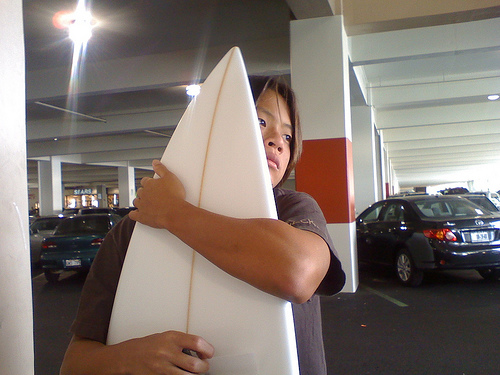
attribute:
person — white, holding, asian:
[55, 77, 344, 374]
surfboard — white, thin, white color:
[106, 43, 301, 374]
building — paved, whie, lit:
[1, 2, 499, 374]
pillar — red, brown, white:
[289, 14, 360, 294]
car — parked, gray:
[357, 195, 499, 285]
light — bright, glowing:
[425, 229, 457, 242]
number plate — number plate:
[470, 230, 488, 245]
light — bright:
[66, 15, 94, 46]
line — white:
[360, 275, 410, 306]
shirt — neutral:
[272, 187, 345, 299]